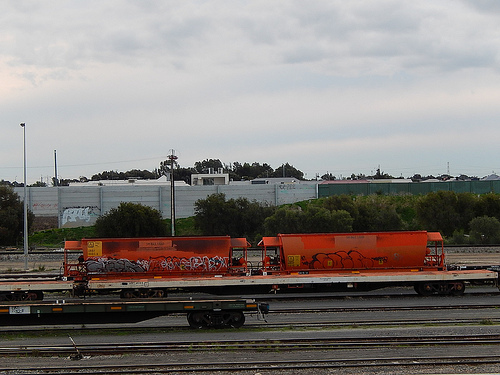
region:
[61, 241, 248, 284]
orange train car on platform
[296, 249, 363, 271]
graffiti on train car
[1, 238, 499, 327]
train moving on tracks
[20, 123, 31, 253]
grey metal light post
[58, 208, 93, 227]
white graffiti on wall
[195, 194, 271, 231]
bush next to tracks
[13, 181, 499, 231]
building by train tracks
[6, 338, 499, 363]
metal and wood train tracks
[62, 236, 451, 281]
metal containers on train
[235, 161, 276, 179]
tree with green leaves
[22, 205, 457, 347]
Train stopped on track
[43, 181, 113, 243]
White graffiti on wall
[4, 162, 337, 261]
Grey wooden wall divider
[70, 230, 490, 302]
Orange train cars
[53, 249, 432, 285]
Grafitti on train car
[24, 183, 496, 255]
Trees next to train tracks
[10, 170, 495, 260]
The trees behind the train are green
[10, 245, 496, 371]
Numerous train track lines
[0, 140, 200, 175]
Telephone wire in background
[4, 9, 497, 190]
Dark cloudy sky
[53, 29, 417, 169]
The sky is cloudy.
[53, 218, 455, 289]
An orange train on the tracks.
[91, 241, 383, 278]
the train cars have grafitti written on it.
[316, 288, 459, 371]
Tracks lined up on the ground.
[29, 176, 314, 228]
A building behind the trees.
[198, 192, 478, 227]
The trees are green and bushy.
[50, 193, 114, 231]
White grafitti on the building.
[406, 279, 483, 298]
The wheels of the train.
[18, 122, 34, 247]
A light pole next to the tracks.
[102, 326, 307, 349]
Green grass on the tracks.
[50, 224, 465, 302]
a train on a track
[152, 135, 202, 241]
a power line behind the train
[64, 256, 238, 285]
graffiti on a train car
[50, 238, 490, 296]
the train is red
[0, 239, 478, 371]
the tracks are brown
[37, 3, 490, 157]
the sky is grey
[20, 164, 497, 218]
the fence is white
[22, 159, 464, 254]
the fence is behind the trees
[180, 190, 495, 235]
the trees have green leaves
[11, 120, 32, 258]
the lightpole is tall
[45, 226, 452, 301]
two orange train cars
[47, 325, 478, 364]
steel railroad tracks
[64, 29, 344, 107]
overcast sky above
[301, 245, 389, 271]
graffiti painted on side of train car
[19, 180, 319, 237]
sound barrier between tracks and buildings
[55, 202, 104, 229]
graffiti painted on sound barrier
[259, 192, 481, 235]
leaves on green bushes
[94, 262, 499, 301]
flatbed rail car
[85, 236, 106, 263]
yellow sticker on front train car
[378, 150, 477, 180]
utility pole and wires